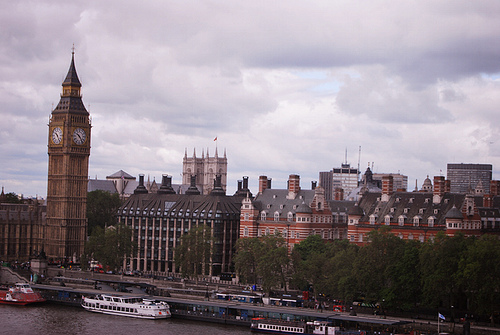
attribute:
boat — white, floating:
[82, 291, 171, 319]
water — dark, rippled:
[0, 300, 255, 334]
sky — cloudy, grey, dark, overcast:
[0, 1, 500, 199]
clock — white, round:
[72, 128, 86, 144]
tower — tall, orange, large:
[44, 43, 93, 257]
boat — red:
[0, 283, 47, 305]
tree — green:
[84, 224, 138, 271]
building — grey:
[448, 164, 493, 194]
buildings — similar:
[240, 175, 483, 254]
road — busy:
[28, 281, 500, 331]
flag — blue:
[213, 135, 219, 142]